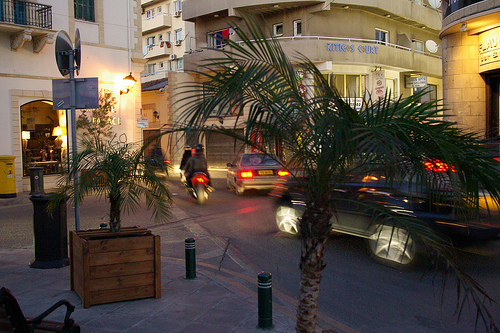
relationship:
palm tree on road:
[134, 13, 498, 330] [317, 238, 498, 331]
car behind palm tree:
[270, 160, 499, 265] [134, 13, 498, 330]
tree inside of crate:
[44, 129, 176, 234] [68, 226, 161, 310]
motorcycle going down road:
[181, 142, 215, 205] [151, 170, 498, 331]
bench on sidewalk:
[3, 287, 81, 330] [1, 243, 135, 331]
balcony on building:
[143, 15, 173, 33] [137, 0, 197, 173]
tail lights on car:
[240, 168, 290, 177] [224, 149, 292, 199]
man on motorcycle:
[184, 150, 206, 180] [181, 142, 215, 205]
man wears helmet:
[184, 150, 206, 180] [194, 144, 204, 154]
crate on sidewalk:
[68, 226, 158, 306] [5, 258, 283, 331]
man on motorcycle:
[184, 142, 213, 174] [180, 171, 219, 206]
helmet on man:
[192, 140, 207, 151] [177, 139, 232, 193]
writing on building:
[327, 42, 380, 57] [142, 0, 453, 190]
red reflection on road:
[237, 203, 254, 217] [151, 170, 498, 331]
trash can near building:
[0, 152, 17, 199] [2, 1, 141, 192]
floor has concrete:
[3, 203, 353, 331] [1, 169, 498, 331]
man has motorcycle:
[183, 144, 213, 189] [186, 163, 216, 203]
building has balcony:
[3, 1, 148, 208] [0, 1, 59, 54]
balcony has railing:
[2, 0, 52, 25] [2, 0, 52, 29]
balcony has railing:
[187, 35, 442, 68] [193, 33, 440, 40]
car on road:
[270, 160, 499, 271] [194, 189, 278, 280]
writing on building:
[326, 42, 380, 55] [178, 3, 433, 127]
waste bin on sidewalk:
[26, 190, 71, 270] [2, 192, 47, 306]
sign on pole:
[46, 61, 129, 124] [58, 104, 105, 300]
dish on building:
[425, 39, 437, 54] [439, 0, 499, 164]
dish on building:
[427, 0, 439, 8] [439, 0, 499, 164]